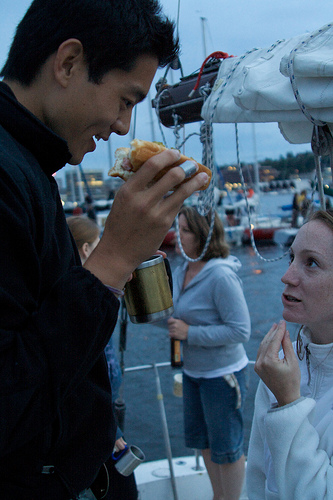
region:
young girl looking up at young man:
[245, 210, 331, 497]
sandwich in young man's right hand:
[110, 140, 217, 192]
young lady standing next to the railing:
[172, 203, 252, 498]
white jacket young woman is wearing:
[241, 329, 330, 496]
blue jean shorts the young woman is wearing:
[181, 366, 249, 465]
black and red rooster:
[153, 49, 233, 127]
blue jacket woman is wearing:
[166, 254, 251, 378]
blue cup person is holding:
[112, 443, 145, 478]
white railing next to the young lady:
[118, 347, 257, 498]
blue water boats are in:
[62, 174, 330, 498]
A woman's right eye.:
[308, 248, 318, 271]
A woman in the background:
[182, 232, 238, 460]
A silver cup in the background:
[122, 444, 143, 477]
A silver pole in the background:
[153, 369, 189, 498]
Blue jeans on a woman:
[210, 379, 242, 447]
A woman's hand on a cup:
[117, 437, 125, 448]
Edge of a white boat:
[149, 461, 177, 499]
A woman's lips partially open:
[282, 289, 301, 299]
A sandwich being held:
[122, 144, 213, 182]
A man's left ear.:
[32, 9, 104, 95]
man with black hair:
[0, 1, 192, 87]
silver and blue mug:
[112, 439, 151, 482]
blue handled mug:
[112, 444, 147, 479]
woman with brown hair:
[180, 203, 237, 261]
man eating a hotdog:
[1, 0, 234, 292]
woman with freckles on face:
[281, 214, 332, 330]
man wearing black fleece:
[0, 156, 123, 496]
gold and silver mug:
[122, 251, 184, 326]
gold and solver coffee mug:
[121, 255, 183, 327]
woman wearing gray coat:
[172, 258, 245, 363]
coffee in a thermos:
[125, 255, 174, 322]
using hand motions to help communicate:
[254, 210, 331, 405]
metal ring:
[180, 159, 199, 178]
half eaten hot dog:
[108, 137, 210, 188]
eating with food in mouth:
[278, 281, 299, 312]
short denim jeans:
[181, 366, 239, 453]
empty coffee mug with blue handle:
[113, 444, 142, 473]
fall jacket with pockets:
[4, 82, 117, 496]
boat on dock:
[164, 124, 290, 249]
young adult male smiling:
[33, 0, 133, 165]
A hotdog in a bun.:
[107, 138, 213, 191]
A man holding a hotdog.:
[0, 0, 211, 499]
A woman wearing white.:
[245, 208, 332, 499]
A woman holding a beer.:
[168, 205, 253, 498]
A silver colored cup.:
[112, 444, 146, 476]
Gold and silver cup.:
[123, 252, 174, 324]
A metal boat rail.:
[122, 360, 178, 499]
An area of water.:
[225, 245, 302, 361]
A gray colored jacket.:
[171, 252, 251, 371]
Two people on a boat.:
[290, 188, 307, 228]